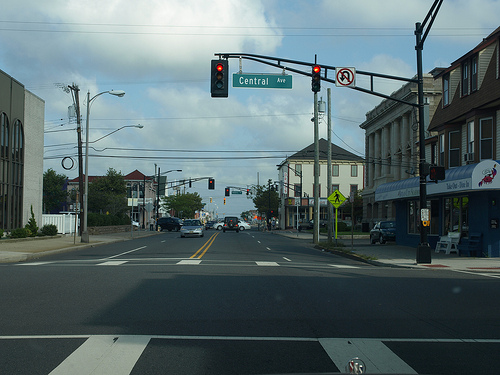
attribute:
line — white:
[4, 330, 499, 349]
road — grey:
[1, 215, 499, 374]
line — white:
[98, 225, 151, 265]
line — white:
[239, 226, 294, 266]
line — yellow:
[188, 226, 221, 261]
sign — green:
[235, 74, 292, 86]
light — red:
[215, 60, 223, 70]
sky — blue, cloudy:
[1, 1, 499, 202]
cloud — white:
[1, 0, 281, 70]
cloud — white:
[290, 4, 499, 48]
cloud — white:
[22, 77, 329, 182]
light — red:
[314, 66, 319, 74]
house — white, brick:
[276, 136, 362, 230]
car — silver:
[181, 218, 207, 238]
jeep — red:
[223, 214, 241, 232]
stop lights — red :
[219, 62, 326, 110]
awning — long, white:
[373, 157, 499, 203]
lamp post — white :
[81, 123, 144, 243]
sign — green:
[192, 37, 329, 122]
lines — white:
[133, 252, 310, 374]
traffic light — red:
[195, 41, 240, 107]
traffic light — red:
[297, 47, 327, 99]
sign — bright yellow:
[328, 189, 347, 239]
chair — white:
[437, 226, 459, 264]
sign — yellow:
[321, 187, 350, 236]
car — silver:
[177, 216, 204, 243]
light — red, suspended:
[311, 64, 321, 91]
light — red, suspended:
[209, 54, 229, 100]